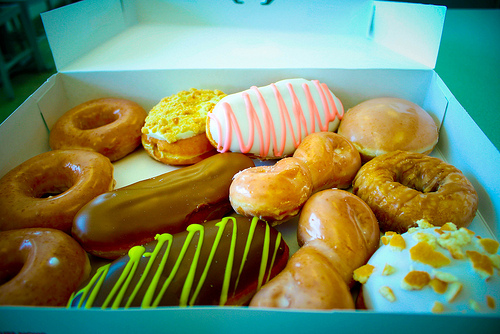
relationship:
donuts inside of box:
[35, 91, 494, 313] [1, 4, 500, 334]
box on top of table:
[1, 4, 500, 334] [455, 13, 500, 91]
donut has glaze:
[222, 78, 341, 140] [222, 98, 316, 135]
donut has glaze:
[101, 240, 275, 303] [105, 244, 244, 309]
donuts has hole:
[47, 96, 148, 163] [82, 112, 115, 130]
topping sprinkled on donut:
[400, 232, 476, 286] [371, 230, 500, 319]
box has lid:
[1, 4, 500, 334] [47, 2, 445, 69]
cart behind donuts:
[1, 0, 40, 87] [35, 91, 494, 313]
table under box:
[455, 13, 500, 91] [1, 4, 500, 334]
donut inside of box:
[1, 225, 82, 304] [1, 4, 500, 334]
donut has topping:
[144, 89, 210, 161] [161, 98, 206, 127]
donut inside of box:
[80, 155, 231, 236] [1, 4, 500, 334]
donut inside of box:
[4, 150, 106, 215] [1, 4, 500, 334]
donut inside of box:
[285, 193, 369, 307] [1, 4, 500, 334]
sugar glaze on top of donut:
[310, 143, 340, 176] [247, 140, 350, 203]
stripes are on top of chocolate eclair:
[157, 237, 208, 289] [101, 240, 275, 303]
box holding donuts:
[1, 4, 500, 334] [35, 91, 494, 313]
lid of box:
[47, 2, 445, 69] [1, 4, 500, 334]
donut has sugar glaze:
[345, 97, 440, 152] [371, 106, 411, 124]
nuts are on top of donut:
[161, 112, 198, 129] [144, 89, 210, 161]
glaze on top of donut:
[150, 132, 166, 141] [144, 89, 210, 161]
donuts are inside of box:
[35, 91, 494, 313] [1, 4, 500, 334]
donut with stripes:
[222, 78, 341, 140] [249, 92, 273, 148]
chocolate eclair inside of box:
[101, 240, 275, 303] [1, 4, 500, 334]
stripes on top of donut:
[157, 237, 208, 289] [101, 240, 275, 303]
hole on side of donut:
[149, 141, 162, 158] [144, 89, 210, 161]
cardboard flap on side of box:
[430, 83, 448, 126] [1, 4, 500, 334]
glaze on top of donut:
[326, 202, 358, 236] [285, 193, 369, 307]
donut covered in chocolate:
[101, 240, 275, 303] [209, 267, 224, 293]